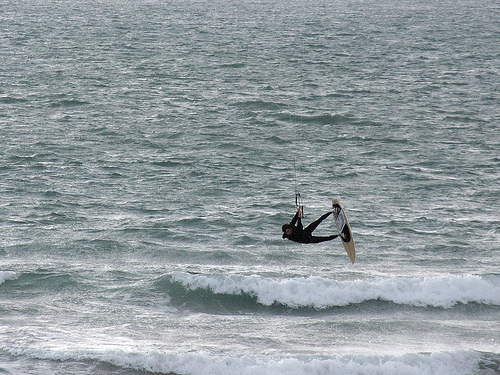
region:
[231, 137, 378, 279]
a person is wind surfing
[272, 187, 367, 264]
the person is wearing black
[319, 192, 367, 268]
the surfboard is yellow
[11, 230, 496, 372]
the water has waves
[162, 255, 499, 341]
the waves are white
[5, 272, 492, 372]
the water is foamy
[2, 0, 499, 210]
the water is calm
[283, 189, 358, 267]
the person has legs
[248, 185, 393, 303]
the person is in the air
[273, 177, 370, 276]
the person is holding a handle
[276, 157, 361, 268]
Man surfboarding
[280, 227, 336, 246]
Man's wetsuit is black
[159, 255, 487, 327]
Crest of wave is white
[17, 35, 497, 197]
Rest of surrounding ocean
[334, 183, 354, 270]
Board is white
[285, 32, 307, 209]
Man grabbing strings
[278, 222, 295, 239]
Man looking down at water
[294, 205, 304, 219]
Both man's hands are white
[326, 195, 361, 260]
Feet attached to board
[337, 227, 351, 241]
Man's right foot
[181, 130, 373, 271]
A young man kite surfing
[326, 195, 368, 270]
A kite surfing board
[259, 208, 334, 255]
a young man on a kit surf board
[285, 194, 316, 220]
handle to the kite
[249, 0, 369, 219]
line from the kite to the handle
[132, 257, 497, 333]
a wave crashing down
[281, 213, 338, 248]
black wetsuit on the man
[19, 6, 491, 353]
the ocean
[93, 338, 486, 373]
a wave crashing down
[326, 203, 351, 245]
foot straps on the board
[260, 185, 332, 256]
man para sailing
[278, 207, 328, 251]
man wearing wet suit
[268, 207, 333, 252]
man wearing black wet suit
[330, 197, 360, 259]
man attached to tan surfboard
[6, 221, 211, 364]
white and green ocean waves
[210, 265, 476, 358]
white and green ocean waves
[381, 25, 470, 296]
white and green ocean waves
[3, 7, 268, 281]
white and green ocean waves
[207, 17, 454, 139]
white and green ocean waves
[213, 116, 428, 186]
white and green ocean waves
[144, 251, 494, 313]
White caps on a breaking wave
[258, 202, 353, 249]
The man is wearing a wet suit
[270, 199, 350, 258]
The wet suit is black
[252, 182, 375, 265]
Kite surfer in the air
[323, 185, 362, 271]
The kite board is white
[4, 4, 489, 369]
One person in the photo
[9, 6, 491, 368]
Photo taken during the day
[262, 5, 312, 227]
The person is holding kite strings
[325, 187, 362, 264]
The person's feet are strapped in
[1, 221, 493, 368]
Two waves breaking